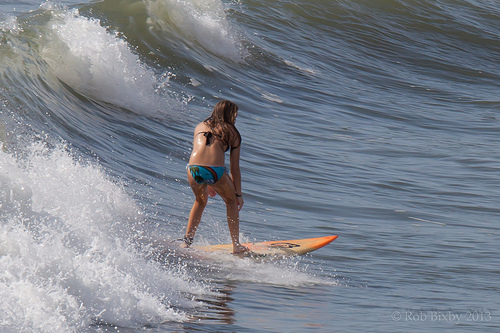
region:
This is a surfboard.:
[118, 222, 358, 272]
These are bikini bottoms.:
[175, 153, 238, 192]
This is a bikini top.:
[178, 118, 246, 159]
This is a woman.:
[163, 61, 275, 282]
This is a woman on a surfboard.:
[112, 76, 349, 301]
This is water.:
[323, 142, 428, 229]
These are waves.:
[1, 12, 283, 102]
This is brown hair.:
[206, 91, 238, 146]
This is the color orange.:
[305, 237, 318, 248]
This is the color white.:
[73, 245, 125, 297]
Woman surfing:
[81, 94, 339, 271]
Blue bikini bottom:
[181, 159, 231, 192]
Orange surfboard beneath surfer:
[80, 225, 340, 265]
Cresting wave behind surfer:
[0, 1, 348, 279]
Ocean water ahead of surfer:
[96, 94, 493, 282]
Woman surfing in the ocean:
[5, 1, 358, 297]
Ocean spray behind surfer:
[1, 8, 369, 274]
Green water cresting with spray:
[73, 5, 203, 87]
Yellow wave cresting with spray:
[77, 3, 203, 83]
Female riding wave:
[27, 8, 344, 266]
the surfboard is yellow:
[147, 221, 352, 271]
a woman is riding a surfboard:
[140, 80, 335, 285]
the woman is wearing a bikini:
[125, 65, 287, 267]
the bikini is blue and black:
[161, 110, 247, 196]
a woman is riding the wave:
[1, 0, 371, 332]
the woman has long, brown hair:
[182, 78, 254, 158]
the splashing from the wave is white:
[3, 120, 315, 332]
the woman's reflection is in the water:
[132, 88, 355, 330]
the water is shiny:
[3, 1, 496, 329]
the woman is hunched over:
[122, 82, 342, 285]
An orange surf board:
[198, 228, 344, 263]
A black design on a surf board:
[264, 241, 302, 252]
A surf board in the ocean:
[168, 221, 350, 274]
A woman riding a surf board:
[179, 91, 259, 270]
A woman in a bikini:
[180, 90, 256, 272]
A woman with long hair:
[177, 85, 254, 270]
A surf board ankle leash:
[170, 233, 196, 248]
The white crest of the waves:
[7, 132, 216, 332]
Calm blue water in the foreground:
[356, 56, 497, 288]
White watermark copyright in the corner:
[392, 303, 495, 328]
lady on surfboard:
[180, 98, 263, 273]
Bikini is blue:
[186, 157, 255, 187]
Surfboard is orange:
[166, 217, 361, 270]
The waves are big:
[43, 17, 269, 130]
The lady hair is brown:
[206, 86, 251, 156]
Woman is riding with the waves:
[96, 90, 344, 322]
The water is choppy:
[31, 15, 198, 312]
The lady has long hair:
[204, 84, 246, 159]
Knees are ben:
[176, 178, 251, 219]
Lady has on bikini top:
[193, 123, 250, 165]